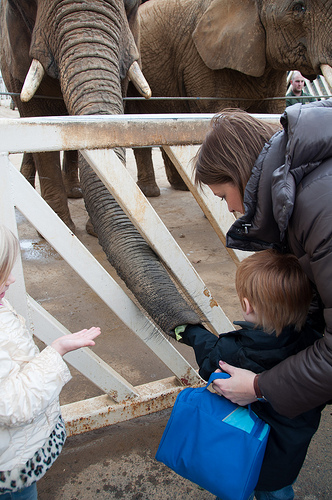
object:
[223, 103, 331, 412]
coat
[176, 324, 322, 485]
coat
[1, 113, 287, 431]
fence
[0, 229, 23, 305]
head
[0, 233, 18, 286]
hair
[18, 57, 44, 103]
tusk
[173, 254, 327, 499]
arm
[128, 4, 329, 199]
elephant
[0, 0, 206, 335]
elephant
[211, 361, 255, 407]
hand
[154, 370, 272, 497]
lunch box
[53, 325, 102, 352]
hand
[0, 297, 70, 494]
coat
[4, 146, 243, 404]
poles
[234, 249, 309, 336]
hair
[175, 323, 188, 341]
leaf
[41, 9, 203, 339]
elephant's trunk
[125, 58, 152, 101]
elephant tusk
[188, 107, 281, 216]
hair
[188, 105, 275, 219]
head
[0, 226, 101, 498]
girl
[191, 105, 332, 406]
mother